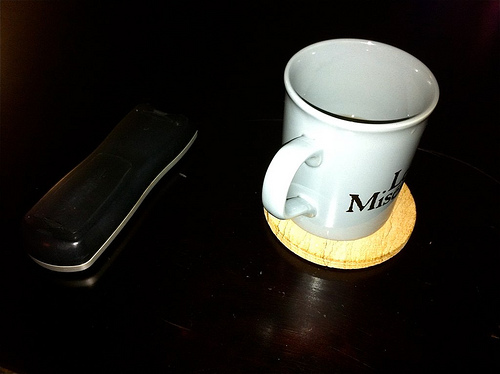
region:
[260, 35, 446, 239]
A white cup on a coaster.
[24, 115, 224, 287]
a case on a table.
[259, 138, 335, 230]
a handle on a coffee cup.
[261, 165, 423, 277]
a coaster under a coffee cup.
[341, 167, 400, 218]
writing on a coffee cup.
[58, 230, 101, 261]
light reflecting on a black surface.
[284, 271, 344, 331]
light reflecting on a table.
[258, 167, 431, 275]
a wooden coaster.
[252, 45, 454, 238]
a drinking glass.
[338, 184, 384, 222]
an m on the side of a cup.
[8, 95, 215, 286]
a television remote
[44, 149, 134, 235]
the battery plate on a television remote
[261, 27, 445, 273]
a mug depicting the play le miserable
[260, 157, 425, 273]
a coaster on a coffee table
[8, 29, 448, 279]
a coffee mug next to a tv remote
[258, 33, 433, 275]
a coffee mug sitting on a coaster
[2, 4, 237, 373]
a wooden table with a television remote on it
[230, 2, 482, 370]
a wooden table with a coffee mug on it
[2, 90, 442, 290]
a television remote next to a coaster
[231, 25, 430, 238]
a empty coffee mug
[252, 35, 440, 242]
White cup on desk.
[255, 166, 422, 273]
Brown coaster under cup.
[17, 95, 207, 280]
Phone on the desk.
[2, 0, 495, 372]
Walnut colored wood on desk.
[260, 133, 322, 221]
Handle on the cup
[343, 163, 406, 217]
black writing on the cup.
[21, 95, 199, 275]
silver color on phone front.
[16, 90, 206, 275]
black bottom on the phone.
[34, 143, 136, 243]
Battery compartment on the phone.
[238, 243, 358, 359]
cup reflection on the desk.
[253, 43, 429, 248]
coffee mug on table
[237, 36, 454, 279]
coffee mug on coast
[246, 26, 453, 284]
coffee mug on a a table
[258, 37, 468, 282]
coffee mug on brown coaster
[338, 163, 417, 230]
black writing on mug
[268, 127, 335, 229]
white handle of mug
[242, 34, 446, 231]
white and black coffee mug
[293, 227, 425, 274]
brown wooden coaster on table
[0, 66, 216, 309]
black and silver remote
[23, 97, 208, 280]
remote control on table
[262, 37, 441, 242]
a coffee mug is white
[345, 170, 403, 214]
black lettering on mug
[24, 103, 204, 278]
a black remote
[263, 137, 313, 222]
handle on a mug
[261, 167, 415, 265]
a cork coaster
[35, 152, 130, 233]
the battery cap on a remote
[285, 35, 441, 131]
the rim of a cup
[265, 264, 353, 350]
reflection of a cup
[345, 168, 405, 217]
black lettering on a cup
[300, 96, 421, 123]
shadow on a cup